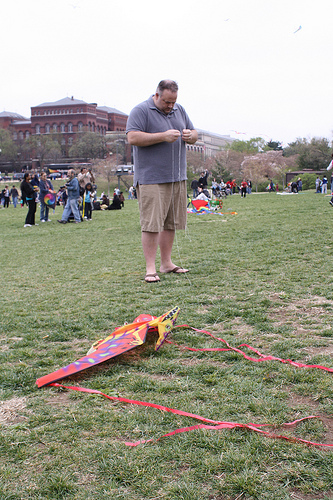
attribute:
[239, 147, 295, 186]
tree — brown, bare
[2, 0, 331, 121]
sky — cloudy, white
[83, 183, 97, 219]
child — walking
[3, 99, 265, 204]
buildings — brick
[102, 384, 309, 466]
tail — red 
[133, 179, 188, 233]
shorts — brown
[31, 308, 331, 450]
kite — yellow , purple, red, large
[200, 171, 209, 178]
arm — upraised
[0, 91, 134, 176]
building — institutional, brick, red, large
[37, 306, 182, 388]
kite — dragon, colorful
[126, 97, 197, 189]
shirt — gray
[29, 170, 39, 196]
child — small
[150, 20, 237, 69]
clouds — white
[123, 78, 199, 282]
man — older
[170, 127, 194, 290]
string — kite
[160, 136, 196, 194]
ribbons — red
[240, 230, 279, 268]
grass — green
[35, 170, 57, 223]
jeans — blue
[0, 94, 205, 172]
building — large, red, brick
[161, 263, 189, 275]
shoe — brown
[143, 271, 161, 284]
shoe — brown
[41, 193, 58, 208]
object — colored, circular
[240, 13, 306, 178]
kite — airborne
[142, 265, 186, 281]
flip flops — brown